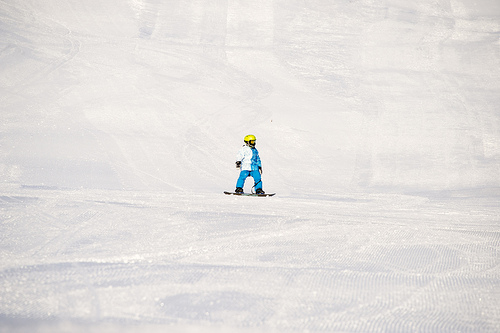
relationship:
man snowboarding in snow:
[234, 133, 266, 194] [133, 184, 204, 205]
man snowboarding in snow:
[234, 133, 266, 194] [53, 229, 125, 254]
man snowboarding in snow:
[234, 133, 266, 194] [306, 240, 376, 272]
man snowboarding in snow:
[234, 133, 266, 194] [393, 235, 445, 257]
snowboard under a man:
[223, 190, 276, 198] [228, 132, 266, 191]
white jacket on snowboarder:
[237, 145, 261, 171] [228, 131, 278, 199]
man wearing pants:
[234, 133, 266, 194] [236, 170, 263, 190]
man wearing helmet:
[234, 133, 266, 194] [240, 135, 255, 145]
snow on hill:
[6, 7, 499, 131] [0, 0, 499, 333]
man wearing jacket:
[234, 133, 266, 194] [235, 146, 262, 174]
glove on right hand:
[224, 154, 240, 184] [257, 160, 268, 168]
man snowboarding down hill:
[234, 133, 266, 194] [153, 203, 479, 233]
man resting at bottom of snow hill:
[234, 133, 266, 194] [204, 202, 471, 310]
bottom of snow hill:
[14, 180, 181, 248] [4, 1, 499, 331]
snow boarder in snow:
[228, 133, 267, 198] [160, 117, 364, 262]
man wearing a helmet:
[234, 133, 266, 194] [238, 138, 272, 153]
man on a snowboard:
[234, 133, 266, 194] [214, 190, 284, 196]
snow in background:
[0, 34, 499, 332] [102, 173, 143, 227]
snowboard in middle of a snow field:
[223, 191, 276, 197] [12, 50, 454, 287]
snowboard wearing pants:
[223, 191, 276, 197] [234, 173, 265, 229]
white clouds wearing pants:
[217, 129, 278, 207] [234, 173, 265, 229]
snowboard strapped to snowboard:
[223, 191, 276, 197] [222, 186, 277, 199]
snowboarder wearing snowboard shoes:
[232, 147, 267, 192] [222, 180, 273, 211]